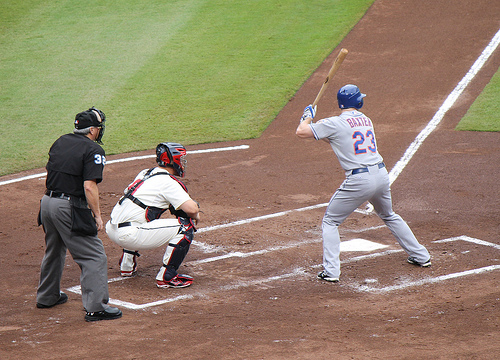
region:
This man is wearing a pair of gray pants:
[331, 183, 376, 322]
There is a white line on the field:
[418, 110, 438, 165]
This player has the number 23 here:
[352, 130, 377, 185]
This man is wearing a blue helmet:
[344, 81, 361, 113]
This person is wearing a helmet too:
[162, 143, 179, 176]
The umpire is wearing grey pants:
[81, 262, 104, 316]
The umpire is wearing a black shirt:
[56, 152, 63, 176]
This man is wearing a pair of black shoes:
[323, 262, 334, 286]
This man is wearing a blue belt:
[353, 164, 370, 188]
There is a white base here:
[345, 232, 369, 280]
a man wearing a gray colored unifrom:
[296, 82, 433, 282]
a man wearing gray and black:
[36, 105, 122, 320]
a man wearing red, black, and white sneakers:
[106, 141, 194, 288]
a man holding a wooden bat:
[293, 49, 435, 280]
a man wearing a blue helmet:
[295, 83, 432, 283]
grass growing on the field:
[0, 0, 374, 175]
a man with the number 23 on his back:
[294, 82, 434, 284]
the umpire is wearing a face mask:
[38, 108, 122, 320]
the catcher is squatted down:
[101, 140, 201, 290]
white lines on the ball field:
[0, 31, 497, 311]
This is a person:
[296, 54, 468, 325]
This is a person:
[108, 121, 265, 353]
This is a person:
[21, 89, 127, 353]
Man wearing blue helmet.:
[332, 90, 396, 108]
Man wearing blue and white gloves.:
[294, 92, 321, 131]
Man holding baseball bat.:
[293, 77, 321, 139]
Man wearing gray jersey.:
[338, 124, 375, 162]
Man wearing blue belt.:
[345, 163, 400, 176]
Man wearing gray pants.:
[334, 181, 356, 201]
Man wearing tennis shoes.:
[301, 265, 358, 294]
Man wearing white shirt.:
[138, 187, 175, 209]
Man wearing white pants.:
[111, 223, 188, 258]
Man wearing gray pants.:
[68, 235, 128, 308]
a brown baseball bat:
[308, 47, 344, 103]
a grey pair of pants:
[35, 190, 106, 310]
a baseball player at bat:
[294, 45, 433, 280]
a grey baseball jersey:
[310, 110, 384, 168]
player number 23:
[349, 129, 376, 156]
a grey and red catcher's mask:
[155, 139, 185, 178]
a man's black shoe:
[82, 308, 121, 320]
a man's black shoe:
[33, 290, 67, 307]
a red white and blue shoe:
[159, 276, 191, 288]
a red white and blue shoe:
[120, 264, 139, 276]